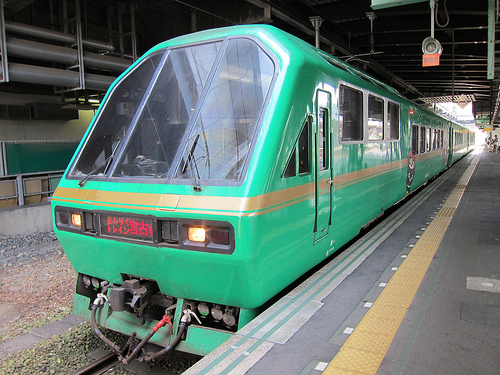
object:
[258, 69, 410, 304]
side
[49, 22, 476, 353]
train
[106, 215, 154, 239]
letters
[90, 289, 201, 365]
wires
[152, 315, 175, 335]
grip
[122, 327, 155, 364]
tube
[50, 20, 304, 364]
front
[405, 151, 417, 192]
design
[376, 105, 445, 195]
side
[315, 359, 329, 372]
square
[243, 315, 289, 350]
color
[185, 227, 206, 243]
light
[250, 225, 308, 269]
green color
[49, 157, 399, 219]
border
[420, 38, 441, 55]
flood light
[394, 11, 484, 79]
ceiling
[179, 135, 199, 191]
wiper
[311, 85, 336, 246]
door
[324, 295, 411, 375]
line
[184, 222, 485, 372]
ground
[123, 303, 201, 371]
hoses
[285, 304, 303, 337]
stripe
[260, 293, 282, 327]
stripe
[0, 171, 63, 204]
railing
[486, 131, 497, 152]
people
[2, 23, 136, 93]
pipes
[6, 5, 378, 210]
wall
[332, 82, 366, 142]
window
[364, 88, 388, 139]
window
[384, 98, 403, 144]
window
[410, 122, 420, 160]
window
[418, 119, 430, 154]
window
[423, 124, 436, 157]
window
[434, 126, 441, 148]
window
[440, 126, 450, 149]
window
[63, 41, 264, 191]
window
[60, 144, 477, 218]
stripe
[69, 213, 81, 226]
headlight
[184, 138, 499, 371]
platform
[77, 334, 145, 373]
tracks